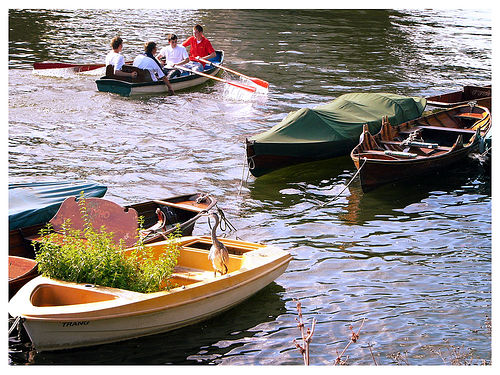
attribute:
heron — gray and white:
[196, 205, 234, 275]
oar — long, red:
[176, 62, 258, 96]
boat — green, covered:
[245, 102, 365, 154]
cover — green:
[314, 93, 444, 138]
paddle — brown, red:
[173, 58, 273, 98]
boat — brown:
[335, 95, 485, 190]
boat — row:
[76, 20, 253, 113]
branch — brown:
[293, 300, 320, 364]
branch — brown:
[334, 317, 366, 363]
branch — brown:
[364, 340, 380, 365]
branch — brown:
[384, 345, 411, 364]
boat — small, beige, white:
[6, 228, 307, 355]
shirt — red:
[187, 36, 203, 54]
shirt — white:
[126, 52, 166, 83]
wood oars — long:
[172, 55, 269, 97]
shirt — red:
[187, 37, 207, 56]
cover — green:
[241, 89, 427, 144]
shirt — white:
[157, 44, 182, 71]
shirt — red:
[174, 34, 216, 68]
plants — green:
[28, 179, 188, 292]